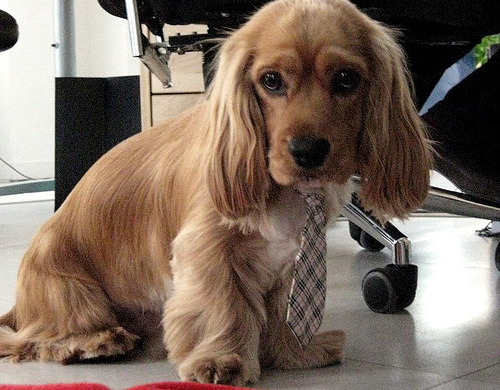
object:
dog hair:
[249, 12, 358, 42]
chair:
[99, 1, 499, 314]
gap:
[431, 41, 497, 110]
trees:
[470, 32, 497, 67]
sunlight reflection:
[413, 212, 486, 318]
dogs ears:
[207, 16, 270, 231]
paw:
[174, 354, 265, 388]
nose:
[287, 135, 335, 169]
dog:
[0, 1, 439, 388]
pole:
[47, 8, 86, 77]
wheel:
[361, 265, 418, 312]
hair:
[355, 53, 434, 216]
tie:
[281, 182, 329, 351]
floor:
[382, 290, 498, 388]